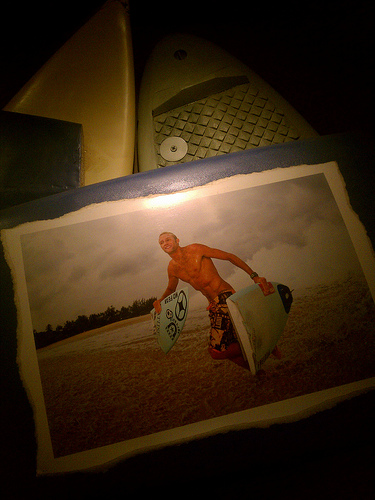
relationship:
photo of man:
[0, 137, 371, 499] [153, 232, 281, 380]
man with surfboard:
[153, 232, 281, 380] [147, 281, 291, 374]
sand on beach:
[33, 278, 373, 460] [59, 334, 211, 398]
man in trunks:
[153, 232, 281, 380] [202, 289, 245, 352]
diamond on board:
[188, 99, 226, 119] [147, 67, 316, 173]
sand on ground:
[33, 278, 373, 460] [33, 259, 374, 459]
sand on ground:
[33, 278, 373, 460] [37, 280, 373, 455]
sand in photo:
[33, 278, 373, 460] [0, 160, 375, 474]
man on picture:
[153, 232, 281, 380] [144, 223, 341, 424]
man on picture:
[125, 228, 279, 431] [89, 179, 318, 379]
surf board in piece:
[223, 280, 294, 375] [146, 287, 195, 362]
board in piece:
[215, 269, 303, 359] [220, 275, 299, 378]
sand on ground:
[33, 278, 373, 460] [84, 330, 236, 407]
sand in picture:
[33, 278, 373, 460] [7, 135, 369, 497]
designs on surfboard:
[161, 294, 186, 339] [145, 283, 191, 358]